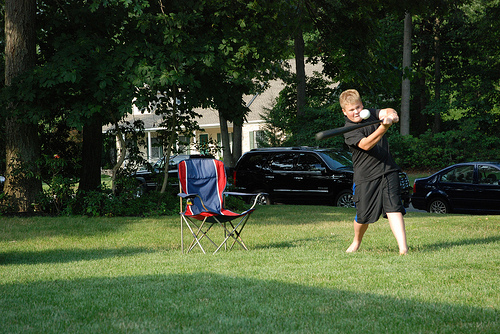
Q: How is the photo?
A: Clear.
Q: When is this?
A: Daytime.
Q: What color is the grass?
A: Green.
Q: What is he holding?
A: Bat.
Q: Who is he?
A: Man.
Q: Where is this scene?
A: Front yard.